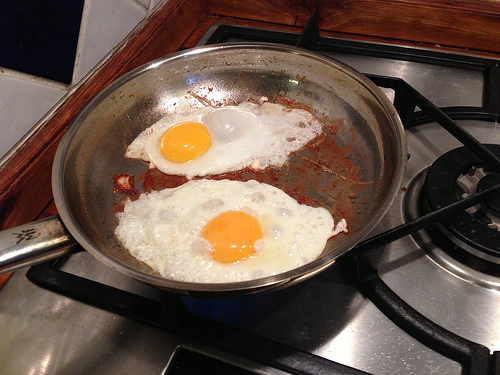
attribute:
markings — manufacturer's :
[8, 224, 38, 246]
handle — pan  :
[0, 208, 87, 273]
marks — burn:
[112, 93, 365, 239]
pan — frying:
[0, 35, 407, 318]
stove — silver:
[6, 27, 496, 373]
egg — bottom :
[116, 175, 349, 282]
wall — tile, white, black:
[0, 5, 160, 180]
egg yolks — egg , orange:
[199, 211, 262, 266]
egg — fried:
[131, 97, 311, 176]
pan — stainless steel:
[29, 20, 412, 325]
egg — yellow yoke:
[164, 175, 342, 284]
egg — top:
[122, 98, 324, 180]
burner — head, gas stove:
[425, 142, 497, 263]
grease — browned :
[292, 155, 353, 200]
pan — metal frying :
[1, 40, 408, 293]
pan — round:
[42, 48, 426, 295]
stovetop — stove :
[56, 20, 496, 373]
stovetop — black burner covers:
[146, 5, 498, 370]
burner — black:
[347, 67, 497, 362]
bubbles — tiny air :
[274, 202, 291, 222]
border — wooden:
[179, 2, 492, 49]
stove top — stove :
[67, 40, 494, 321]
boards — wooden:
[1, 1, 498, 372]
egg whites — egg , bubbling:
[210, 107, 292, 154]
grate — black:
[299, 62, 485, 367]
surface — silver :
[293, 69, 484, 368]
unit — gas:
[386, 75, 483, 256]